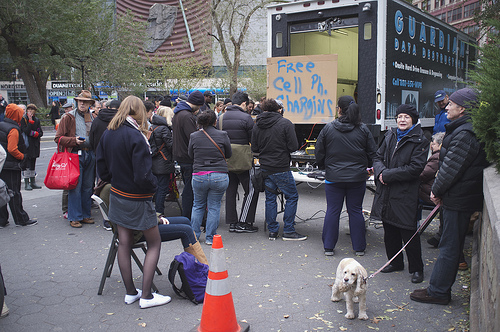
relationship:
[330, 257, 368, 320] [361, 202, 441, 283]
dog on leash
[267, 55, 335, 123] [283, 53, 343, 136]
sign for free cell phone chargers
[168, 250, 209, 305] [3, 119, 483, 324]
backpack laying on ground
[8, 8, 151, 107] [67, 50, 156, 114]
tree in distance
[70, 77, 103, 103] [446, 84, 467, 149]
hat on mans head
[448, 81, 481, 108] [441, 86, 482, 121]
hat on mans head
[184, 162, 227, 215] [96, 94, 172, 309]
jeans on woman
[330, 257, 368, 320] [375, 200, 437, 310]
dog on a leash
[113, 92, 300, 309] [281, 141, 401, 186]
people standing at cellphone charging-station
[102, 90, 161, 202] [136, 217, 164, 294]
woman wearing black nylon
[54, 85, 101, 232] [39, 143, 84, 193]
man with  shopping bag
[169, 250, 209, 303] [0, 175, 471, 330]
backpack on ground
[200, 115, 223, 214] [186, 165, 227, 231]
woman wearing jeans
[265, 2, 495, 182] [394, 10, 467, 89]
truck with lettering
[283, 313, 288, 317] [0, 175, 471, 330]
leaves scattered on ground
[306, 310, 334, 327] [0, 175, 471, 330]
leaves scattered on ground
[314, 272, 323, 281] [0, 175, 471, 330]
leaves scattered on ground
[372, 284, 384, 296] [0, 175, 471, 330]
leaves scattered on ground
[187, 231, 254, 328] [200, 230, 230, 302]
cone with gray strips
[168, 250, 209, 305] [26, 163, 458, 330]
backpack with black straps on ground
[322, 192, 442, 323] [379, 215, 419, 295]
dog on a leash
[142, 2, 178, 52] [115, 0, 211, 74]
tarp hanging from a structure